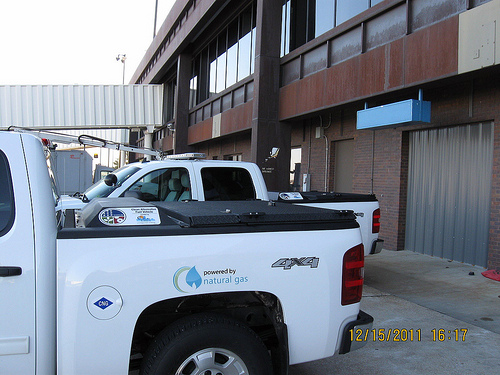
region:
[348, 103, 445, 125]
A blue box attached to an overhang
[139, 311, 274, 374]
A black tire on a white truck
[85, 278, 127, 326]
A round white gas tank cover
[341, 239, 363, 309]
A red tail light on a white truck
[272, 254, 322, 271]
Gray numbers on the side of a white truck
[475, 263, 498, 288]
A red rag on the ground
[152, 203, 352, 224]
A black cover on the back of a pick up truck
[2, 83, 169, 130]
A white walkway attached to a building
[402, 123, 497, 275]
A metal door near a brick wall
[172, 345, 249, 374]
A silver hubcap on a white truck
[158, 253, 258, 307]
Natural Gas Logo for Truck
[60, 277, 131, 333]
The Gas Tank of a Truck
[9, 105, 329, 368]
Government Owned Pickup Trucks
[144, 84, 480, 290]
A White Pickup Truck at Loading Dock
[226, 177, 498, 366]
Time stamping your photos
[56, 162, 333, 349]
Logos on the Side of a Truck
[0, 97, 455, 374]
Pickups at a Loading Dock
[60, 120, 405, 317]
Government Fleet Vehicles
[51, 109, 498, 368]
Spotting Trucks at Work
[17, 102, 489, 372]
Government Using Energy Efficient Vehicles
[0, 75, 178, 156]
metal walkway connected to a building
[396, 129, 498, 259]
metal garage door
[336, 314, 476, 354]
date and time stamp on a picture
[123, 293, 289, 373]
tire on a vehicle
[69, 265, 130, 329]
gas cover on a vehicle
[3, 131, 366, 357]
a white pickup truck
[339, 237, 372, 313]
tail light on a vehicle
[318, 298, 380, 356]
bumper on a vehicle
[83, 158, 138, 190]
spotlight on a vehicle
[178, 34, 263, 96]
windows on a building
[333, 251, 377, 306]
red tail light on truck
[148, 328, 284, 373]
large black wheel with silver rims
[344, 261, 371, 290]
red lines on red tail light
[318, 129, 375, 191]
large brown door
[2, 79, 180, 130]
white container with wide lines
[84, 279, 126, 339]
large silver circle with blue logo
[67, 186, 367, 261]
black cab on back of white truck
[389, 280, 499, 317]
dirty asphalt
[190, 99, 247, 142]
large white line on building railing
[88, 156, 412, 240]
white cam truck with black bed